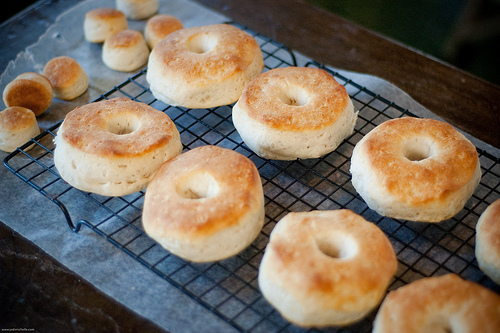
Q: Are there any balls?
A: Yes, there is a ball.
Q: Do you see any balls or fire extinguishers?
A: Yes, there is a ball.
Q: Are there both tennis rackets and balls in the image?
A: No, there is a ball but no rackets.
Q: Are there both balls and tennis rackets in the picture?
A: No, there is a ball but no rackets.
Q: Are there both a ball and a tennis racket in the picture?
A: No, there is a ball but no rackets.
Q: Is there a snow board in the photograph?
A: No, there are no snowboards.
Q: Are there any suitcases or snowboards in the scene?
A: No, there are no snowboards or suitcases.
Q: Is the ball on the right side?
A: No, the ball is on the left of the image.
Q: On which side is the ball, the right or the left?
A: The ball is on the left of the image.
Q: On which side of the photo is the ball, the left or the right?
A: The ball is on the left of the image.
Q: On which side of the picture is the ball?
A: The ball is on the left of the image.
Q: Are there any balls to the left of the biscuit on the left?
A: Yes, there is a ball to the left of the biscuit.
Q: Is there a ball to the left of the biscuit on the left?
A: Yes, there is a ball to the left of the biscuit.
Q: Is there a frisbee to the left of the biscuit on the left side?
A: No, there is a ball to the left of the biscuit.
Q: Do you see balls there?
A: Yes, there is a ball.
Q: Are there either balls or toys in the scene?
A: Yes, there is a ball.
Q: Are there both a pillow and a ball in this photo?
A: No, there is a ball but no pillows.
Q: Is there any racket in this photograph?
A: No, there are no rackets.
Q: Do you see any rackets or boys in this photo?
A: No, there are no rackets or boys.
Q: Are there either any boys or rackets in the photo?
A: No, there are no rackets or boys.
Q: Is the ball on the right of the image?
A: No, the ball is on the left of the image.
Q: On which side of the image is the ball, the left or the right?
A: The ball is on the left of the image.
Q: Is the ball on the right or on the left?
A: The ball is on the left of the image.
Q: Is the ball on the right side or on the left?
A: The ball is on the left of the image.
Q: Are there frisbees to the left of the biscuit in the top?
A: No, there is a ball to the left of the biscuit.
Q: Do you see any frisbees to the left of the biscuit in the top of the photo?
A: No, there is a ball to the left of the biscuit.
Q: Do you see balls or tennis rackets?
A: Yes, there is a ball.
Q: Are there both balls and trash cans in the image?
A: No, there is a ball but no trash cans.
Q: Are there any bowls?
A: No, there are no bowls.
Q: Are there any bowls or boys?
A: No, there are no bowls or boys.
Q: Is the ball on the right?
A: No, the ball is on the left of the image.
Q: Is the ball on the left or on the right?
A: The ball is on the left of the image.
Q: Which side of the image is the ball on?
A: The ball is on the left of the image.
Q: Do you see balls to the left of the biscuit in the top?
A: Yes, there is a ball to the left of the biscuit.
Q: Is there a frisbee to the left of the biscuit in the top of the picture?
A: No, there is a ball to the left of the biscuit.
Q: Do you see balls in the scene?
A: Yes, there is a ball.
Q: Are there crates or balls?
A: Yes, there is a ball.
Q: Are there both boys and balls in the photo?
A: No, there is a ball but no boys.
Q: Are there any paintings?
A: No, there are no paintings.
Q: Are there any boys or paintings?
A: No, there are no paintings or boys.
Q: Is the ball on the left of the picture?
A: Yes, the ball is on the left of the image.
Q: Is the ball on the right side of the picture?
A: No, the ball is on the left of the image.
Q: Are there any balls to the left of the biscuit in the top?
A: Yes, there is a ball to the left of the biscuit.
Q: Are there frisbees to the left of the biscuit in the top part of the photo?
A: No, there is a ball to the left of the biscuit.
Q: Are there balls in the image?
A: Yes, there is a ball.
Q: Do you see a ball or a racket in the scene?
A: Yes, there is a ball.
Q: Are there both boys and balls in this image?
A: No, there is a ball but no boys.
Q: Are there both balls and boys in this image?
A: No, there is a ball but no boys.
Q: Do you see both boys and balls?
A: No, there is a ball but no boys.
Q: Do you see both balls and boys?
A: No, there is a ball but no boys.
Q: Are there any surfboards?
A: No, there are no surfboards.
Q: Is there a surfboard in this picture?
A: No, there are no surfboards.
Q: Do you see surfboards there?
A: No, there are no surfboards.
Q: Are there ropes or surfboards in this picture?
A: No, there are no surfboards or ropes.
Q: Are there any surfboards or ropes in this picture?
A: No, there are no surfboards or ropes.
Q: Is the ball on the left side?
A: Yes, the ball is on the left of the image.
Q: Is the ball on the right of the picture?
A: No, the ball is on the left of the image.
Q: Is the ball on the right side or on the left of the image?
A: The ball is on the left of the image.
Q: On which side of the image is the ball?
A: The ball is on the left of the image.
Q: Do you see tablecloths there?
A: No, there are no tablecloths.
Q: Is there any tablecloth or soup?
A: No, there are no tablecloths or soup.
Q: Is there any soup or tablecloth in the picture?
A: No, there are no tablecloths or soup.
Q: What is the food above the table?
A: The food is a biscuit.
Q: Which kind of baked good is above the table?
A: The food is a biscuit.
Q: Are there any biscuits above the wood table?
A: Yes, there is a biscuit above the table.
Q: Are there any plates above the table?
A: No, there is a biscuit above the table.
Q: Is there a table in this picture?
A: Yes, there is a table.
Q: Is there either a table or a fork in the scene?
A: Yes, there is a table.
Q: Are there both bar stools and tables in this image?
A: No, there is a table but no bar stools.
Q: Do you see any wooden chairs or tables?
A: Yes, there is a wood table.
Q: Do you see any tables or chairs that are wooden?
A: Yes, the table is wooden.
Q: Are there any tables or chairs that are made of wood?
A: Yes, the table is made of wood.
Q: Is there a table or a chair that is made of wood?
A: Yes, the table is made of wood.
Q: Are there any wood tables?
A: Yes, there is a wood table.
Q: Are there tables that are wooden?
A: Yes, there is a table that is wooden.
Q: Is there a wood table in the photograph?
A: Yes, there is a table that is made of wood.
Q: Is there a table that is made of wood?
A: Yes, there is a table that is made of wood.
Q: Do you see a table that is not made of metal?
A: Yes, there is a table that is made of wood.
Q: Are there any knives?
A: No, there are no knives.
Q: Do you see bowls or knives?
A: No, there are no knives or bowls.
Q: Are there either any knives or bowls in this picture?
A: No, there are no knives or bowls.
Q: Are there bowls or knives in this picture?
A: No, there are no knives or bowls.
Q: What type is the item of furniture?
A: The piece of furniture is a table.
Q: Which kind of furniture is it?
A: The piece of furniture is a table.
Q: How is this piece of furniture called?
A: This is a table.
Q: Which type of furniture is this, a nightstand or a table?
A: This is a table.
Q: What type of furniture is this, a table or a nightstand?
A: This is a table.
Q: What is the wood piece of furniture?
A: The piece of furniture is a table.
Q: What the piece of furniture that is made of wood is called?
A: The piece of furniture is a table.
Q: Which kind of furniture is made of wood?
A: The furniture is a table.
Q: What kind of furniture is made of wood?
A: The furniture is a table.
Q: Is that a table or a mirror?
A: That is a table.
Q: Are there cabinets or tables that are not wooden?
A: No, there is a table but it is wooden.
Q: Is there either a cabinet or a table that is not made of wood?
A: No, there is a table but it is made of wood.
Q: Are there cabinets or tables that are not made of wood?
A: No, there is a table but it is made of wood.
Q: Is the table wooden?
A: Yes, the table is wooden.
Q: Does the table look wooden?
A: Yes, the table is wooden.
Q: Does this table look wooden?
A: Yes, the table is wooden.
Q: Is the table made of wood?
A: Yes, the table is made of wood.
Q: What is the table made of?
A: The table is made of wood.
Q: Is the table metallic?
A: No, the table is wooden.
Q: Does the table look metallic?
A: No, the table is wooden.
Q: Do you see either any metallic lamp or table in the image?
A: No, there is a table but it is wooden.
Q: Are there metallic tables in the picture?
A: No, there is a table but it is wooden.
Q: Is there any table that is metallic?
A: No, there is a table but it is wooden.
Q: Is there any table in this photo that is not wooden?
A: No, there is a table but it is wooden.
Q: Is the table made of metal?
A: No, the table is made of wood.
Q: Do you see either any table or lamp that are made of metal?
A: No, there is a table but it is made of wood.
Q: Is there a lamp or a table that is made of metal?
A: No, there is a table but it is made of wood.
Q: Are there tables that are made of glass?
A: No, there is a table but it is made of wood.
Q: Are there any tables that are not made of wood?
A: No, there is a table but it is made of wood.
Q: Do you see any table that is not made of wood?
A: No, there is a table but it is made of wood.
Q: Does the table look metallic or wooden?
A: The table is wooden.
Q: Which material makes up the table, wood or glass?
A: The table is made of wood.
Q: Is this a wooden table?
A: Yes, this is a wooden table.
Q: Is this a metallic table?
A: No, this is a wooden table.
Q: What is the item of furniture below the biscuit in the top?
A: The piece of furniture is a table.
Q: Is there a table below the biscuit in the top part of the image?
A: Yes, there is a table below the biscuit.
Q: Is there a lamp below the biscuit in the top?
A: No, there is a table below the biscuit.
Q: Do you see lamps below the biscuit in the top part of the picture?
A: No, there is a table below the biscuit.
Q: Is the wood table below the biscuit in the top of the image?
A: Yes, the table is below the biscuit.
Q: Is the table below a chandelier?
A: No, the table is below the biscuit.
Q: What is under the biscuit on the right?
A: The table is under the biscuit.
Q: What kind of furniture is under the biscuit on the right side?
A: The piece of furniture is a table.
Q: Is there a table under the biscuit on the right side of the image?
A: Yes, there is a table under the biscuit.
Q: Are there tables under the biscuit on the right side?
A: Yes, there is a table under the biscuit.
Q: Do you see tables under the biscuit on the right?
A: Yes, there is a table under the biscuit.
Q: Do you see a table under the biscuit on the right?
A: Yes, there is a table under the biscuit.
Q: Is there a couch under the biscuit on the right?
A: No, there is a table under the biscuit.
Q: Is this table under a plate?
A: No, the table is under a biscuit.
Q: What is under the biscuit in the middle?
A: The table is under the biscuit.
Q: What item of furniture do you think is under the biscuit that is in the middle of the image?
A: The piece of furniture is a table.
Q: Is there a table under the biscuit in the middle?
A: Yes, there is a table under the biscuit.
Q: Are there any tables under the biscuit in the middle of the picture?
A: Yes, there is a table under the biscuit.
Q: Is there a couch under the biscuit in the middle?
A: No, there is a table under the biscuit.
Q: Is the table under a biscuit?
A: Yes, the table is under a biscuit.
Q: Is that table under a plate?
A: No, the table is under a biscuit.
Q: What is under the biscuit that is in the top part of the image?
A: The table is under the biscuit.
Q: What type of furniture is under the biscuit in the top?
A: The piece of furniture is a table.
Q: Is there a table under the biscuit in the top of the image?
A: Yes, there is a table under the biscuit.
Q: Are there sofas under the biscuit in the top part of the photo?
A: No, there is a table under the biscuit.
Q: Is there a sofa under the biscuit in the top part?
A: No, there is a table under the biscuit.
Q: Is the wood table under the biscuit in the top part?
A: Yes, the table is under the biscuit.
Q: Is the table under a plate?
A: No, the table is under the biscuit.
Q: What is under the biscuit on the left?
A: The table is under the biscuit.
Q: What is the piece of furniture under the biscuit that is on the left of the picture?
A: The piece of furniture is a table.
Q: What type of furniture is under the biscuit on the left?
A: The piece of furniture is a table.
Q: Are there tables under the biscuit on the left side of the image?
A: Yes, there is a table under the biscuit.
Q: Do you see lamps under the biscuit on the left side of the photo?
A: No, there is a table under the biscuit.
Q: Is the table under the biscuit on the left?
A: Yes, the table is under the biscuit.